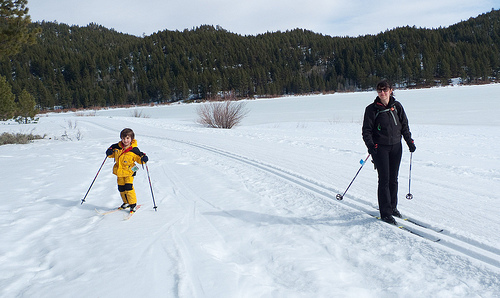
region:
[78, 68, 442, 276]
Two people in snow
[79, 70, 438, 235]
Two people in the snow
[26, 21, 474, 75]
Large amounts of trees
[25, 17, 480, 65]
Large amounts of trees in the background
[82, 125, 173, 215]
A boy dressed in yellow and black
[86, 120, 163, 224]
A boy is smiling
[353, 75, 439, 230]
A woman is smiling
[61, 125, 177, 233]
A boy is skiing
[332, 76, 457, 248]
A woman is skiing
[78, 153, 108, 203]
a child's snow pole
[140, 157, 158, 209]
a child's snow pole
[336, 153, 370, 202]
an adult's snow pole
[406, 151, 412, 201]
an adult's snow pole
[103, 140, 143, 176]
a yellow and black winter coat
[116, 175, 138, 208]
yellow and black snow pants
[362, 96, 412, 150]
a black winter coat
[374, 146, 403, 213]
a pair of black snow pants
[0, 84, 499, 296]
a snow covered field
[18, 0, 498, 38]
a cloudy blue sky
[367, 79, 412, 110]
head of a person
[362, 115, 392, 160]
arm of a person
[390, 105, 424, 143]
arm of a person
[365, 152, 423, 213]
leg of a person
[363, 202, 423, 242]
feet of a person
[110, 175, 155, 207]
leg of a person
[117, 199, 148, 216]
feet of a person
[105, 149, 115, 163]
arm of a person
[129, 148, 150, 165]
arm of a person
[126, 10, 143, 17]
white clouds in blue sky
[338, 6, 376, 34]
white clouds in blue sky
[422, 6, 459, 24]
white clouds in blue sky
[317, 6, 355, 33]
white clouds in blue sky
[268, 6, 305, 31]
white clouds in blue sky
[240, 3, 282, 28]
white clouds in blue sky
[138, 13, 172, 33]
white clouds in blue sky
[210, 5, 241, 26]
white clouds in blue sky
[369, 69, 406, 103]
head of a person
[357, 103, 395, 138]
arm of a person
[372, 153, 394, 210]
leg of a person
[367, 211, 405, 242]
feet of a person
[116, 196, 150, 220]
feet of a person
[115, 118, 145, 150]
a head of a person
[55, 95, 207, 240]
person on a ski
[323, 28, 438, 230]
person on a ski